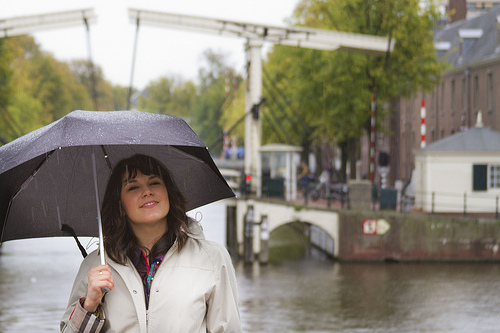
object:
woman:
[60, 153, 239, 332]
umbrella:
[0, 109, 237, 292]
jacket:
[60, 210, 241, 332]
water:
[283, 257, 418, 313]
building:
[383, 10, 499, 187]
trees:
[293, 0, 451, 209]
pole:
[420, 95, 427, 149]